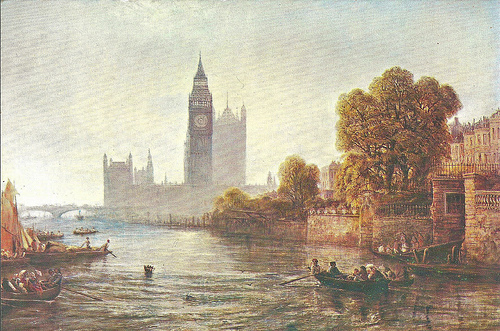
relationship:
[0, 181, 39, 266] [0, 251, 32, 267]
sail of boat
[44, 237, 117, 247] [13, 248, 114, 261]
people on rowboat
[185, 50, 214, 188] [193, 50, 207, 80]
clock tower with spires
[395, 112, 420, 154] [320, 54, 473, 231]
leaves on tree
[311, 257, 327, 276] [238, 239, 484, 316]
man in rowboat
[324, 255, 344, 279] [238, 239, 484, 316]
people in rowboat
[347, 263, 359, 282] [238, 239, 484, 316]
people in rowboat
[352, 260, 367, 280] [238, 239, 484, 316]
people in rowboat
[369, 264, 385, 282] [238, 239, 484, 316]
people in rowboat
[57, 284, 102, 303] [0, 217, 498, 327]
oar in water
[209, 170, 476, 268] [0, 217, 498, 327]
walls along water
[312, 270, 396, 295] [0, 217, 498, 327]
rowboat in water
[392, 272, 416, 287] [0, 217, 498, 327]
rowboat in water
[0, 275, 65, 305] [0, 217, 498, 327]
rowboat in water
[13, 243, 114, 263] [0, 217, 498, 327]
rowboat in water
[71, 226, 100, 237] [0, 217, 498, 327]
boat in water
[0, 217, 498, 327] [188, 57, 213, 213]
water with clock tower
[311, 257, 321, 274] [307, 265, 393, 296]
man rowing rowboat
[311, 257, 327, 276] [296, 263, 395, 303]
man rowing in boat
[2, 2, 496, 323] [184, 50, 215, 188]
painting on clock tower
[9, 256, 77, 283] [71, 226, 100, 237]
people rowing boat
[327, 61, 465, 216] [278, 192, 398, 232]
trees by waters edge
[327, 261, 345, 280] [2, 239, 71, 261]
people rowing goods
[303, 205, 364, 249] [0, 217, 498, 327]
wall by water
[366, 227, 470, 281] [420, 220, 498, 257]
boat by dock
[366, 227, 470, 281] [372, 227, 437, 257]
boat unloading people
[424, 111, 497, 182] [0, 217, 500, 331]
buildings overlooking water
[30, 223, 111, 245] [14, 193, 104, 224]
boat under bridge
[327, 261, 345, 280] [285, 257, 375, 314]
people riding boat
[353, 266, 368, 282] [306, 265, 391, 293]
people riding boat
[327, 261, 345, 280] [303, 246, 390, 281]
people riding boat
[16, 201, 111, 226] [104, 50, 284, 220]
bridge into city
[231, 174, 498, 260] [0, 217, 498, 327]
wall along water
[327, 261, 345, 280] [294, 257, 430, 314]
people in boat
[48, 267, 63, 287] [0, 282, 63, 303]
people in rowboat